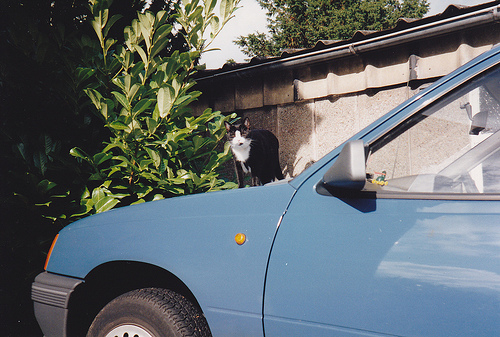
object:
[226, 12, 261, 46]
sky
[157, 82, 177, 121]
leaf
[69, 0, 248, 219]
tree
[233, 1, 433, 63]
tree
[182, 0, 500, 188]
structure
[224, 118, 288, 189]
cat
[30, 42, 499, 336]
car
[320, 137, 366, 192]
mirror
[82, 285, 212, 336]
tire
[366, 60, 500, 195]
window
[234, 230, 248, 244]
reflector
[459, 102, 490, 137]
rearview mirror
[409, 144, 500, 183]
windshield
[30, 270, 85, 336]
bumper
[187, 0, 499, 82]
roof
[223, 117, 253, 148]
head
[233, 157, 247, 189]
leg